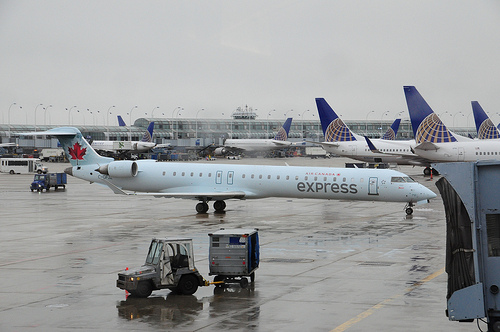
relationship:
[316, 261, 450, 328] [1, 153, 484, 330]
painted on tarmac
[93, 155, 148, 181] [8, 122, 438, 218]
engine of airplane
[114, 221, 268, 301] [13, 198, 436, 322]
truck on tarmac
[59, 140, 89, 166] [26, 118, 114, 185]
leaf painted on plane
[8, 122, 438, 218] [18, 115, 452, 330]
airplane on top of tarmac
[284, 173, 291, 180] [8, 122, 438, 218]
window built into airplane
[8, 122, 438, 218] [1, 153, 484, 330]
airplane sitting on tarmac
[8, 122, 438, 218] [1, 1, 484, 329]
airplane parked during day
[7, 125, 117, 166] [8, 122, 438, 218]
tail wing belonging to airplane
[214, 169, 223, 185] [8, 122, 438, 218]
door leading to airplane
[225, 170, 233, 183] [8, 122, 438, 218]
door leading to airplane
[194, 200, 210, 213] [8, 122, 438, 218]
wheel mounted on airplane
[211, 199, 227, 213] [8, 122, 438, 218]
wheel mounted on airplane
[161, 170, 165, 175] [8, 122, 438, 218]
window built into airplane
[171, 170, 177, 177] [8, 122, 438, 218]
window built into airplane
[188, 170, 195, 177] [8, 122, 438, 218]
window built into airplane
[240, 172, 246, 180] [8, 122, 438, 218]
window built into airplane